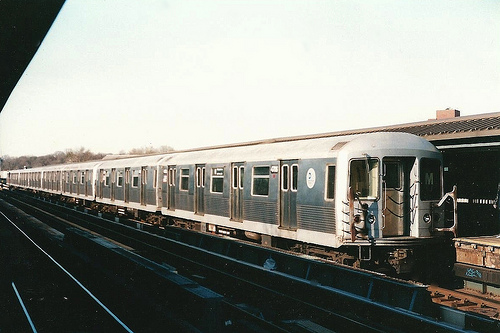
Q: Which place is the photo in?
A: It is at the train station.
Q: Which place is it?
A: It is a train station.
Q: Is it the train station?
A: Yes, it is the train station.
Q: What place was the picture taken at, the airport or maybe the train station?
A: It was taken at the train station.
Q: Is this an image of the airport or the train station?
A: It is showing the train station.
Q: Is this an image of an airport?
A: No, the picture is showing a train station.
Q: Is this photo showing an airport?
A: No, the picture is showing a train station.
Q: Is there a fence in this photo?
A: No, there are no fences.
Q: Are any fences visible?
A: No, there are no fences.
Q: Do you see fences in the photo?
A: No, there are no fences.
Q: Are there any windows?
A: Yes, there is a window.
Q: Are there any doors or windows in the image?
A: Yes, there is a window.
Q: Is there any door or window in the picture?
A: Yes, there is a window.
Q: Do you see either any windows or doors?
A: Yes, there is a window.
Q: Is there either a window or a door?
A: Yes, there is a window.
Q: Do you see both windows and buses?
A: No, there is a window but no buses.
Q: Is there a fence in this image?
A: No, there are no fences.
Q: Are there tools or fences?
A: No, there are no fences or tools.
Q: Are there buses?
A: No, there are no buses.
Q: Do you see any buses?
A: No, there are no buses.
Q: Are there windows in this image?
A: Yes, there is a window.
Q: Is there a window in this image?
A: Yes, there is a window.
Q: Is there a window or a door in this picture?
A: Yes, there is a window.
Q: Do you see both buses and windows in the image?
A: No, there is a window but no buses.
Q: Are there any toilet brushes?
A: No, there are no toilet brushes.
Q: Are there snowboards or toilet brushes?
A: No, there are no toilet brushes or snowboards.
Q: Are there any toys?
A: No, there are no toys.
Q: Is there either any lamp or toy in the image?
A: No, there are no toys or lamps.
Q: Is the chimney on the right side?
A: Yes, the chimney is on the right of the image.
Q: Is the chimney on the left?
A: No, the chimney is on the right of the image.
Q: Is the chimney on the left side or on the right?
A: The chimney is on the right of the image.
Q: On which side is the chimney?
A: The chimney is on the right of the image.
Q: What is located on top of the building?
A: The chimney is on top of the building.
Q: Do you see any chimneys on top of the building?
A: Yes, there is a chimney on top of the building.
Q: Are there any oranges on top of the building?
A: No, there is a chimney on top of the building.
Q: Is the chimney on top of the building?
A: Yes, the chimney is on top of the building.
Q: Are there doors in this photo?
A: Yes, there is a door.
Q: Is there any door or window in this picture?
A: Yes, there is a door.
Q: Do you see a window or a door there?
A: Yes, there is a door.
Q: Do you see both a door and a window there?
A: Yes, there are both a door and a window.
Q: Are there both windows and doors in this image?
A: Yes, there are both a door and a window.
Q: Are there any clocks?
A: No, there are no clocks.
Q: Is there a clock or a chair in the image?
A: No, there are no clocks or chairs.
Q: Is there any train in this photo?
A: Yes, there is a train.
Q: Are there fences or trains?
A: Yes, there is a train.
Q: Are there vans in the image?
A: No, there are no vans.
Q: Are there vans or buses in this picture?
A: No, there are no vans or buses.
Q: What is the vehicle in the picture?
A: The vehicle is a train.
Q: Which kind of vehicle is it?
A: The vehicle is a train.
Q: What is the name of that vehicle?
A: That is a train.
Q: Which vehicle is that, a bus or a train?
A: That is a train.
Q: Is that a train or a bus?
A: That is a train.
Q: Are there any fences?
A: No, there are no fences.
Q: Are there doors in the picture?
A: Yes, there is a door.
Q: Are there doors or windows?
A: Yes, there is a door.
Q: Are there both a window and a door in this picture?
A: Yes, there are both a door and a window.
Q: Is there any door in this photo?
A: Yes, there is a door.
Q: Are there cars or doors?
A: Yes, there is a door.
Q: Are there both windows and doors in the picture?
A: Yes, there are both a door and a window.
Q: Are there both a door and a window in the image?
A: Yes, there are both a door and a window.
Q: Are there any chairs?
A: No, there are no chairs.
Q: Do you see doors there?
A: Yes, there is a door.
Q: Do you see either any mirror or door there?
A: Yes, there is a door.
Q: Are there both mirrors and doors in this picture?
A: No, there is a door but no mirrors.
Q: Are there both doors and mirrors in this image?
A: No, there is a door but no mirrors.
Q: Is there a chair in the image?
A: No, there are no chairs.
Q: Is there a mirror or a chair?
A: No, there are no chairs or mirrors.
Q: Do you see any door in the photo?
A: Yes, there is a door.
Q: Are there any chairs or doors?
A: Yes, there is a door.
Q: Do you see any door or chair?
A: Yes, there is a door.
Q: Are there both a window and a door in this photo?
A: Yes, there are both a door and a window.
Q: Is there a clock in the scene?
A: No, there are no clocks.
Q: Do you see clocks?
A: No, there are no clocks.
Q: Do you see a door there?
A: Yes, there is a door.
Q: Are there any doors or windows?
A: Yes, there is a door.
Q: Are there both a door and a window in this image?
A: Yes, there are both a door and a window.